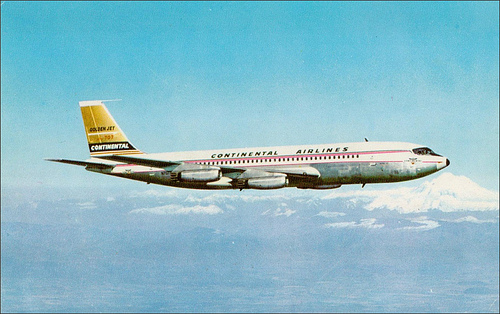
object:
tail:
[78, 100, 148, 157]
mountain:
[352, 171, 499, 216]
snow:
[361, 173, 497, 215]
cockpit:
[413, 146, 450, 168]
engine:
[177, 168, 220, 181]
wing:
[96, 155, 318, 192]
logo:
[208, 146, 348, 159]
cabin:
[182, 150, 440, 167]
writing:
[211, 145, 355, 163]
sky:
[0, 0, 499, 189]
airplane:
[46, 99, 452, 190]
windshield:
[412, 146, 442, 157]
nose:
[445, 157, 451, 167]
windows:
[355, 154, 358, 159]